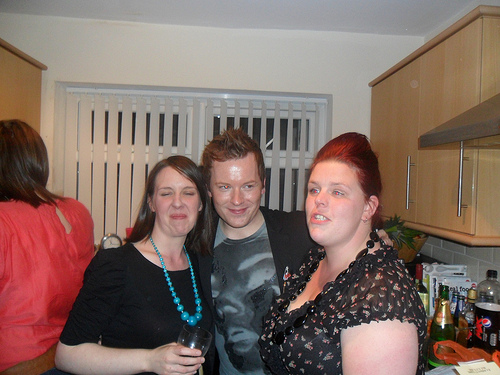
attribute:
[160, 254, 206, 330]
necklace — plastic, blue, faux pearl, big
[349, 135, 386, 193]
hair — bright red, red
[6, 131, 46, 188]
hair — brown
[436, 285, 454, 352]
bottle — open, wine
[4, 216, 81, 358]
shirt — red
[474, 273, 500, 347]
bottle — empty, plastic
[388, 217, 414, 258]
plant — green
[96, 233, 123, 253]
clock — silver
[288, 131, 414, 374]
woman — red-headed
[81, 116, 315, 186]
blinds — white, open, vertical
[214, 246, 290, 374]
shirt — gray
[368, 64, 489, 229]
cabinets — tan, wooden, wood, closed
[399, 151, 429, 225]
handle — silver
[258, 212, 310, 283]
coat — black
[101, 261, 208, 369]
dress — black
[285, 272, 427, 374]
dress — floral print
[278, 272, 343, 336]
necklace — black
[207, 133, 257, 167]
hair — light brown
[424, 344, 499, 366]
shopping bag — plastic, orange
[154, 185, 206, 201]
eyes — closed